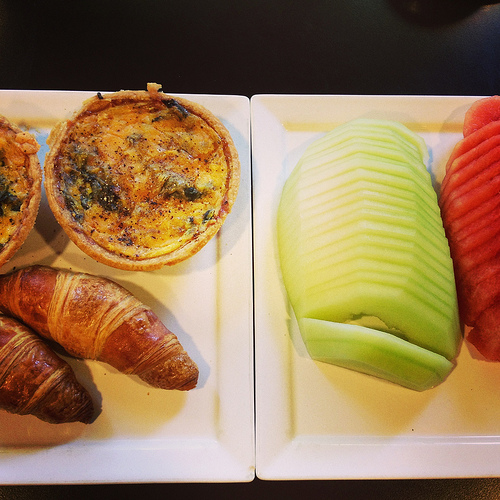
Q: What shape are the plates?
A: Square.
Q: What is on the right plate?
A: Honey dew and watermelons.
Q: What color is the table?
A: Black.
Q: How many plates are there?
A: Two.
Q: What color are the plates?
A: White.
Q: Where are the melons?
A: On the right plate.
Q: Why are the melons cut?
A: To make them easier to eat.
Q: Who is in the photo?
A: Nobody.